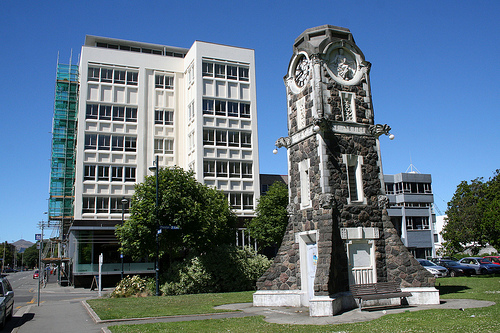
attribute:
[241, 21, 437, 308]
tower — stone, small, white, large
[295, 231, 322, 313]
door — white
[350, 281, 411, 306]
bench — wooden, gray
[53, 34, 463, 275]
building — large, white, tallest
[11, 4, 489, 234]
sky — blue, clear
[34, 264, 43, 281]
car — red, parked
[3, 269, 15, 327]
car — parked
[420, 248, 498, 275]
cars — parked, lined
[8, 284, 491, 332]
sidewalk — cement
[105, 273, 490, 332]
grass — green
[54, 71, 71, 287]
fire escape — green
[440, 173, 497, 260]
trees — green, leafy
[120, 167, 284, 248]
trees — leafy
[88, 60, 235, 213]
windows — paneled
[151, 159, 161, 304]
pole — large, metal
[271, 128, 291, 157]
light — hanging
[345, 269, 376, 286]
rail — white